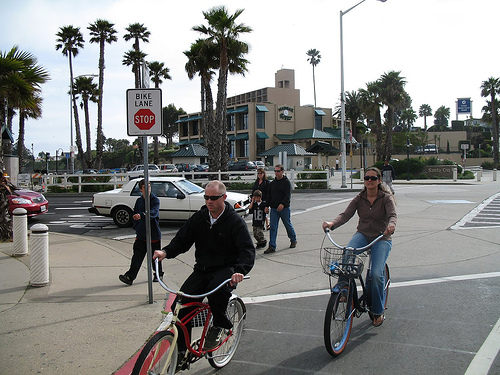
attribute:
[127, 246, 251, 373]
red bike — large, metal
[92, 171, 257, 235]
white car — small, metal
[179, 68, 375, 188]
house —  large,  wide,   brown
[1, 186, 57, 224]
car —  short,  red,  metal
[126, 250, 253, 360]
bike — RED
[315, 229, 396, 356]
bike — small, metal, blue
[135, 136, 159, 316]
pole — tall, long, metal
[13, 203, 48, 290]
posts — small, white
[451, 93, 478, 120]
billboard — blue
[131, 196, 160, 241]
sweater — blue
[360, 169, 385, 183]
sunglasses — dark, black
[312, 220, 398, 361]
bike — blue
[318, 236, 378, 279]
basket — black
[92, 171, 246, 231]
car — white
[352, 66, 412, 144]
tree — tall, green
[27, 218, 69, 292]
column — white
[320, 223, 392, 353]
bicycle — blue